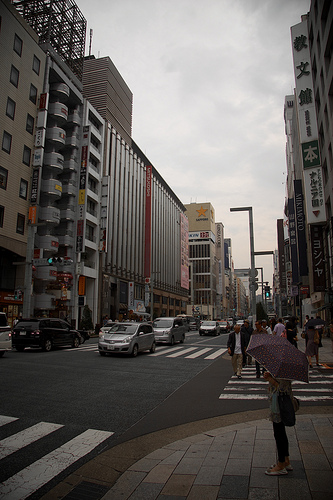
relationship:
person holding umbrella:
[263, 369, 293, 474] [245, 333, 310, 382]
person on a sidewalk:
[263, 369, 293, 474] [98, 402, 330, 496]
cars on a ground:
[98, 321, 157, 356] [0, 330, 332, 498]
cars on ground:
[98, 321, 157, 356] [0, 330, 332, 498]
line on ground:
[0, 427, 113, 499] [0, 330, 332, 498]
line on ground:
[205, 345, 230, 358] [0, 330, 332, 498]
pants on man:
[231, 352, 243, 373] [228, 324, 249, 379]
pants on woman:
[271, 421, 290, 460] [262, 363, 295, 473]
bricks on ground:
[105, 409, 329, 497] [103, 407, 329, 496]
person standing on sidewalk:
[263, 369, 293, 474] [214, 422, 259, 485]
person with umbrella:
[263, 369, 293, 474] [254, 336, 304, 382]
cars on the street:
[100, 317, 185, 349] [100, 354, 144, 399]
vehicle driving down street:
[12, 316, 82, 351] [108, 362, 169, 395]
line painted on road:
[0, 427, 113, 499] [145, 374, 184, 420]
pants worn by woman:
[271, 421, 290, 460] [257, 362, 298, 470]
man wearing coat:
[227, 322, 245, 378] [242, 329, 245, 348]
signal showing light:
[40, 251, 68, 272] [43, 251, 52, 265]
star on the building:
[195, 201, 210, 217] [186, 197, 219, 313]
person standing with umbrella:
[263, 369, 293, 474] [249, 329, 302, 377]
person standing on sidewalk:
[263, 369, 293, 474] [213, 434, 259, 492]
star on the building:
[195, 201, 210, 217] [196, 198, 217, 307]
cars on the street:
[98, 321, 157, 356] [156, 372, 184, 405]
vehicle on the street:
[19, 313, 86, 354] [134, 377, 186, 406]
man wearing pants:
[227, 322, 245, 378] [231, 356, 241, 375]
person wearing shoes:
[263, 369, 293, 474] [261, 460, 290, 481]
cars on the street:
[98, 321, 157, 356] [120, 377, 156, 403]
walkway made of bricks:
[152, 432, 264, 493] [160, 472, 196, 495]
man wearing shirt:
[212, 313, 244, 371] [232, 333, 240, 354]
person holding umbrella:
[263, 369, 293, 474] [252, 324, 310, 383]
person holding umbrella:
[263, 369, 293, 474] [255, 336, 297, 377]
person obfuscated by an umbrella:
[263, 369, 293, 474] [241, 329, 299, 377]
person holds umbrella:
[263, 369, 293, 474] [242, 327, 312, 387]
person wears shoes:
[263, 369, 293, 474] [258, 459, 294, 475]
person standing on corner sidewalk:
[260, 366, 294, 473] [40, 403, 331, 495]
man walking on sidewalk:
[227, 322, 245, 378] [221, 327, 330, 363]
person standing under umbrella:
[263, 369, 293, 474] [245, 330, 312, 384]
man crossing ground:
[227, 322, 245, 378] [0, 330, 332, 498]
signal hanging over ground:
[46, 254, 64, 266] [0, 330, 332, 498]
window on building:
[184, 201, 225, 319] [186, 244, 194, 258]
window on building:
[207, 243, 210, 257] [185, 237, 226, 326]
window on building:
[199, 231, 211, 239] [180, 198, 227, 322]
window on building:
[207, 243, 210, 257] [178, 200, 226, 328]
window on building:
[207, 243, 210, 257] [179, 201, 222, 328]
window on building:
[207, 243, 210, 257] [183, 199, 230, 328]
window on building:
[207, 243, 210, 257] [180, 198, 227, 322]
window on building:
[203, 240, 211, 258] [178, 200, 226, 328]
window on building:
[207, 243, 210, 257] [182, 201, 218, 320]